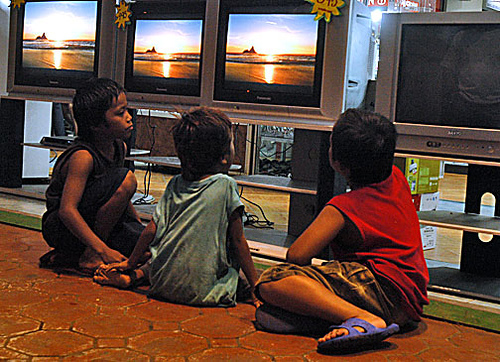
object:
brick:
[129, 348, 162, 354]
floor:
[1, 222, 498, 359]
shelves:
[1, 94, 498, 329]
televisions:
[197, 0, 373, 131]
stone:
[469, 337, 498, 359]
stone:
[415, 331, 432, 343]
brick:
[399, 346, 430, 361]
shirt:
[154, 172, 246, 307]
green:
[176, 228, 194, 243]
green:
[213, 181, 227, 193]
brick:
[7, 240, 30, 249]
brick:
[158, 342, 191, 346]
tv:
[0, 0, 115, 103]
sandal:
[311, 313, 403, 354]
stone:
[79, 281, 117, 307]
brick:
[71, 314, 105, 338]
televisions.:
[106, 0, 215, 111]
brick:
[239, 341, 282, 356]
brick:
[0, 347, 21, 359]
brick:
[247, 352, 273, 360]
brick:
[223, 309, 255, 311]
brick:
[74, 318, 100, 335]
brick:
[447, 328, 499, 352]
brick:
[3, 236, 30, 270]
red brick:
[128, 313, 167, 327]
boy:
[252, 107, 427, 352]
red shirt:
[326, 165, 432, 319]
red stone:
[254, 332, 276, 345]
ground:
[3, 210, 498, 359]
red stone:
[30, 299, 69, 331]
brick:
[175, 322, 193, 329]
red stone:
[106, 282, 144, 301]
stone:
[2, 250, 8, 269]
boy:
[94, 104, 258, 309]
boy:
[37, 78, 136, 273]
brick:
[150, 308, 173, 324]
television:
[373, 11, 498, 159]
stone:
[368, 347, 376, 360]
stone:
[103, 345, 120, 362]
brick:
[20, 274, 24, 290]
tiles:
[6, 329, 96, 361]